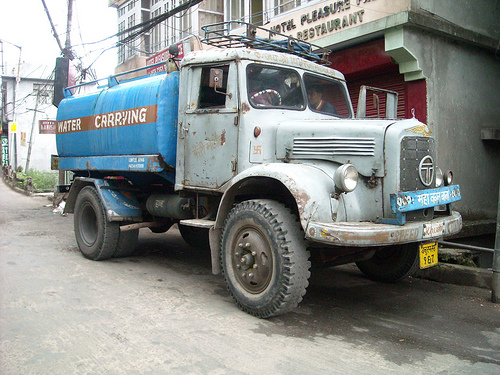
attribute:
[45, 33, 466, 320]
truck — large, blue, old, water carrier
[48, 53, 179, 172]
tank — blue, carrying water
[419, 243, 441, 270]
license plate — yellow, on the front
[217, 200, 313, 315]
front tire — on the right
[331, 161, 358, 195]
headlight — on the right, on the front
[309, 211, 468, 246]
bumper — on the front, rusty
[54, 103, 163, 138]
sign — brown, words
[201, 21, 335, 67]
rack — blue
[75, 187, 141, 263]
rear tire — on the right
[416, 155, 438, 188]
logo — silver, metal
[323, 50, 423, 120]
garage — red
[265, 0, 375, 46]
sign — for a restaurant